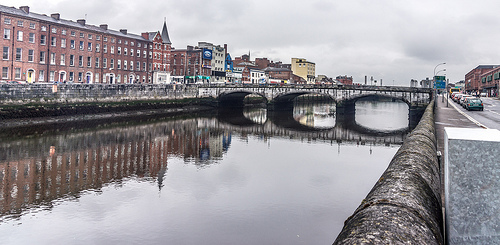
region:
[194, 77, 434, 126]
A long bridge over water.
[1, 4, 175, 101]
A very long building with many windows.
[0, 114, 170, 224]
Reflection of large red brick building in water.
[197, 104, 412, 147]
Reflection of a long bridge in the water.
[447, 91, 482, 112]
Line of cars on the right of the water.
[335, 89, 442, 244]
A long gray and white speckled pipe on the right of the water.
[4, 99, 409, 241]
Large waterway through the city.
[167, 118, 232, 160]
Reflection of the second building on the water.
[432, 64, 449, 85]
Three street lights in consession on the right.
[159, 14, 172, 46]
Pointy black roof to the left of the bridge.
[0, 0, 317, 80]
a row of buildings.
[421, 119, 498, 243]
a cement slab near a river.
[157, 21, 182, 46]
a tower on a building.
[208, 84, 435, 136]
a bridge crossing water.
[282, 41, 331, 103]
a tall building in the distance.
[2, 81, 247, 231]
the reflection of buildings in a river.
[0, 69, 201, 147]
the side of a river.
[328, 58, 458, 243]
a side of a large river.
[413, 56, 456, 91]
street lights near a river.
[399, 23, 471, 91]
a large gray cloud.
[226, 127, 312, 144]
a reflection in the water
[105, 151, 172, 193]
a reflection in the water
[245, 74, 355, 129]
a bridge over the water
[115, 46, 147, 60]
the windows in a building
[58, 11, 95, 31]
a roof of a building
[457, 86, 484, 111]
cars on a road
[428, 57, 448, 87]
lights over a road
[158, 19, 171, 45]
steeple of a building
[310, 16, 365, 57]
clouds in the sky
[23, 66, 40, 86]
a door way to a building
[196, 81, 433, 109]
stone bridge over some water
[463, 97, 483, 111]
car parked on the street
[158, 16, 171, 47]
the top of a tower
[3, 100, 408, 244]
river in the city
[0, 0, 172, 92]
large red building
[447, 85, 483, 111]
row of cars parked on the street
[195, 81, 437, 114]
bridge crossing the river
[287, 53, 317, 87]
tan colored building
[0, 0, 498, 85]
cloudy sky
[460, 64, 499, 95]
red building with green roof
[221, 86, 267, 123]
The opening on the left under the overpass.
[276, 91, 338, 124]
The opening in the middle under the overpass.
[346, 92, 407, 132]
The opening on the right under the overpass.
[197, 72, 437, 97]
The overpass above the water.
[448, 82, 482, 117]
The cars on the right side.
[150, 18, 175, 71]
The building on the left with a pointy roof.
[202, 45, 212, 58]
The blue sign on the building on the left.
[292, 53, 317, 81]
The beige/yellow building on the left in the distance.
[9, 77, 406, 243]
The water way in the middle of the photo.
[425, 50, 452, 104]
The street lights on the right.